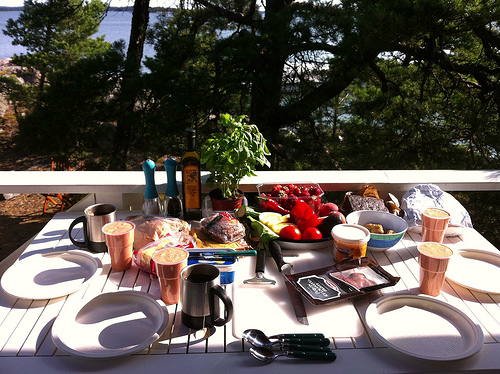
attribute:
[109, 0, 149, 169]
trees — distant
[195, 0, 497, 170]
trees — distant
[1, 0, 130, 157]
trees — distant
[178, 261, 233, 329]
mug — coffee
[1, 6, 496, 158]
water — blue body 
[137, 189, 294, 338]
picnic table — white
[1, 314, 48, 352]
boards — white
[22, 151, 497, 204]
railing — white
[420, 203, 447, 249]
vessel — drinking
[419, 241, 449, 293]
vessel — drinking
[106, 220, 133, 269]
glass — drinking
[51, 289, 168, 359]
plate — white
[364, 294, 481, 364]
plate — white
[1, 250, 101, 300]
plate — white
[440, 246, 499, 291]
plate — white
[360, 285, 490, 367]
plate — paper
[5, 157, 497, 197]
railing — white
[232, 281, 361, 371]
spoons — large, grouped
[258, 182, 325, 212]
bowl — clear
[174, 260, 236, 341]
vessel — drinking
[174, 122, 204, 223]
bottle — tall, balsalmic vinegar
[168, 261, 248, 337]
mug — silver, black, coffee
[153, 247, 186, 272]
drink — creamy 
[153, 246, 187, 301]
cup — colorful